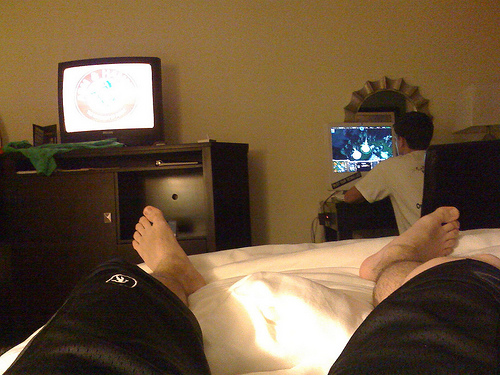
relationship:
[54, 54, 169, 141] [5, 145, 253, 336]
television sitting on cabinet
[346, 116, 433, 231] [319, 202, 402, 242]
boy sitting at desk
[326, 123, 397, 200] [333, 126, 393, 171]
computer has screen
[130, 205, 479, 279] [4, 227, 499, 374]
feet are on bed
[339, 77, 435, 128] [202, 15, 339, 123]
mirror on wall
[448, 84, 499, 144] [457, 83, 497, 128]
lamp has shade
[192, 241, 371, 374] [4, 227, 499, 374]
sheet on bed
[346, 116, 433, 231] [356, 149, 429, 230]
boy has short sleeves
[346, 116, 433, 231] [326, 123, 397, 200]
boy looking at computer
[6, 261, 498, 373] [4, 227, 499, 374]
legs are on bed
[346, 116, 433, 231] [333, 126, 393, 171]
boy watching screen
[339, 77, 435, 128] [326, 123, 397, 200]
mirror behind computer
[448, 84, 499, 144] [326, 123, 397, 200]
lamp beside computer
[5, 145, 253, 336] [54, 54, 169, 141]
cabinet holding television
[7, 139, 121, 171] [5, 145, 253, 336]
cloth on cabinet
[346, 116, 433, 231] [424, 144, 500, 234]
boy in sitting in chair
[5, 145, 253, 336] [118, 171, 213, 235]
cabinet has an open section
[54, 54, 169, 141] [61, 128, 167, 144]
television has black edge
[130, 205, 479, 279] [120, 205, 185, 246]
feet have toes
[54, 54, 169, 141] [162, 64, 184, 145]
television has shadow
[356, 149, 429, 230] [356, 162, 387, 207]
short sleeves has short sleeves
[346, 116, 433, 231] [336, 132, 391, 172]
boy playing game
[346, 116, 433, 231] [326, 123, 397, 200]
boy sitting at computer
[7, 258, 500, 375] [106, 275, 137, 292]
shorts have white lettering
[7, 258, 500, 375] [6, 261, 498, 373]
shorts are on legs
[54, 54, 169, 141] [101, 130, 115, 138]
television has lettering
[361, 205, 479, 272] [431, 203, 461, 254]
foot has toes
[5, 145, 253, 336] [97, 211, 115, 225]
cabinet has knob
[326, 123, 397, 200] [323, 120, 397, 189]
computer has monitor